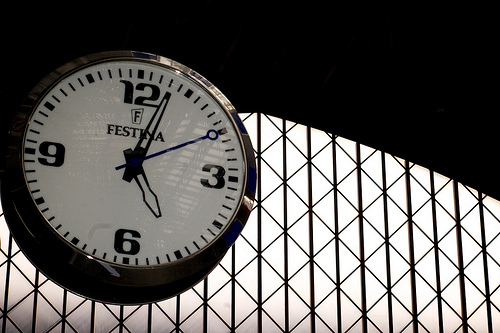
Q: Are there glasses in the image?
A: No, there are no glasses.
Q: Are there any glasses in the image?
A: No, there are no glasses.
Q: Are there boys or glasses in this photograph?
A: No, there are no glasses or boys.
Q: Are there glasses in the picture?
A: No, there are no glasses.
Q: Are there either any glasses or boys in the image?
A: No, there are no glasses or boys.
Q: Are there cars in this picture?
A: No, there are no cars.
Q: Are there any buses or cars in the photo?
A: No, there are no cars or buses.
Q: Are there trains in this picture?
A: No, there are no trains.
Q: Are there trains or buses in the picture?
A: No, there are no trains or buses.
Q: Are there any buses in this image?
A: No, there are no buses.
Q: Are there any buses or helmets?
A: No, there are no buses or helmets.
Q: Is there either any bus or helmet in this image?
A: No, there are no buses or helmets.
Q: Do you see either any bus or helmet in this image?
A: No, there are no buses or helmets.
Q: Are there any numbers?
A: Yes, there are numbers.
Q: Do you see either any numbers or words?
A: Yes, there are numbers.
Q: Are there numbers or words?
A: Yes, there are numbers.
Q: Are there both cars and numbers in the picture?
A: No, there are numbers but no cars.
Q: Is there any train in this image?
A: No, there are no trains.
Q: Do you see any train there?
A: No, there are no trains.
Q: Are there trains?
A: No, there are no trains.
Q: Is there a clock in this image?
A: Yes, there is a clock.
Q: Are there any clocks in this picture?
A: Yes, there is a clock.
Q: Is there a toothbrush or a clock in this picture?
A: Yes, there is a clock.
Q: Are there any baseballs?
A: No, there are no baseballs.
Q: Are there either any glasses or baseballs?
A: No, there are no baseballs or glasses.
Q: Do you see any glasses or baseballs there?
A: No, there are no baseballs or glasses.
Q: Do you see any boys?
A: No, there are no boys.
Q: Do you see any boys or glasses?
A: No, there are no boys or glasses.